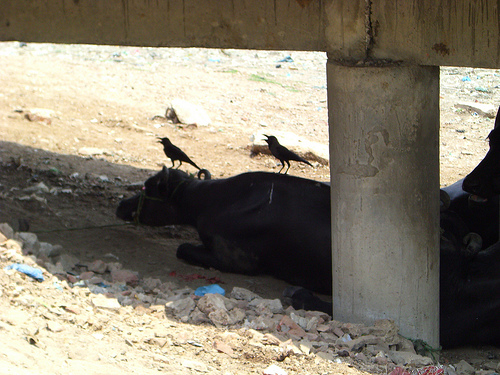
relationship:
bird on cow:
[262, 133, 314, 175] [117, 167, 499, 351]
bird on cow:
[158, 137, 201, 169] [117, 167, 499, 351]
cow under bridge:
[117, 167, 499, 351] [1, 0, 500, 349]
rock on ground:
[164, 292, 195, 325] [1, 43, 500, 375]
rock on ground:
[14, 265, 45, 282] [1, 43, 500, 375]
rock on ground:
[251, 297, 282, 312] [1, 43, 500, 375]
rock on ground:
[24, 106, 61, 124] [1, 43, 500, 375]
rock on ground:
[86, 260, 107, 274] [1, 43, 500, 375]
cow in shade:
[117, 167, 499, 351] [0, 141, 499, 375]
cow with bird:
[117, 167, 499, 351] [262, 133, 314, 175]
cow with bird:
[117, 167, 499, 351] [158, 137, 201, 169]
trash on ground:
[196, 284, 225, 299] [1, 43, 500, 375]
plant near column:
[402, 339, 455, 370] [326, 62, 440, 354]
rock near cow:
[251, 297, 282, 312] [117, 167, 499, 351]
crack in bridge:
[361, 0, 381, 67] [1, 0, 500, 349]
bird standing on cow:
[262, 133, 314, 175] [117, 167, 499, 351]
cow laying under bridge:
[117, 167, 499, 351] [1, 0, 500, 349]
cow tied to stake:
[117, 167, 499, 351] [18, 218, 29, 233]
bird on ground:
[262, 133, 314, 175] [1, 43, 500, 375]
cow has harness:
[117, 167, 499, 351] [136, 174, 192, 225]